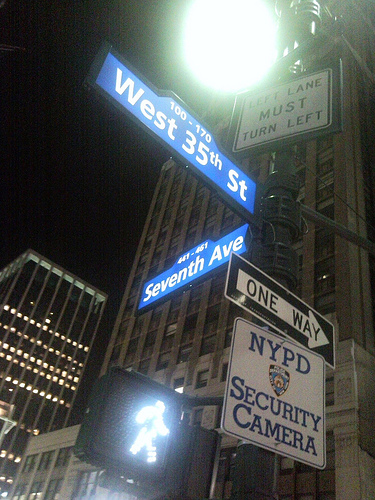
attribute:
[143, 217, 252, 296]
street sign — blue, white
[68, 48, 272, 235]
sign — lit, pedestrian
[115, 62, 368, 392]
building — tall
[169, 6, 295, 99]
light — bright, white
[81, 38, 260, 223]
street sign — blue, white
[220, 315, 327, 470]
sign — blue, white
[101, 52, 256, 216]
street sign — white, blue